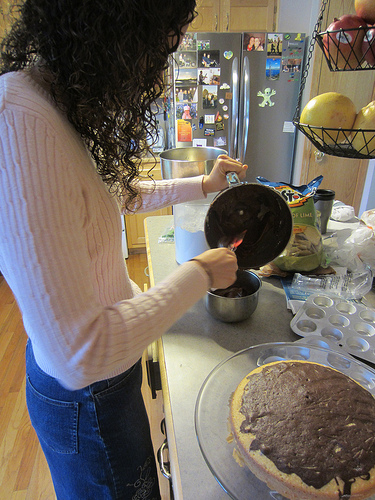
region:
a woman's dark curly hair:
[0, 0, 202, 214]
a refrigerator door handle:
[229, 56, 239, 164]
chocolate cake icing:
[208, 185, 280, 265]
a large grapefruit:
[296, 92, 357, 145]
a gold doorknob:
[313, 147, 323, 161]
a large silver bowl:
[157, 145, 230, 183]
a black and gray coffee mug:
[311, 189, 334, 236]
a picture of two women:
[240, 31, 267, 52]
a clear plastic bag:
[290, 267, 372, 294]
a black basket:
[295, 118, 373, 158]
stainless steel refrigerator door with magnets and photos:
[242, 31, 296, 170]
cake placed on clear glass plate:
[193, 340, 369, 496]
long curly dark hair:
[66, 19, 160, 204]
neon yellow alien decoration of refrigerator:
[254, 81, 278, 111]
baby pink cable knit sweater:
[0, 69, 204, 385]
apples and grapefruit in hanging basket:
[291, 1, 374, 161]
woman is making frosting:
[196, 157, 291, 322]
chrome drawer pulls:
[157, 435, 173, 485]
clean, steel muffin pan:
[290, 288, 374, 360]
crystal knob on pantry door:
[312, 149, 324, 164]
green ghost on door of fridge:
[251, 83, 287, 108]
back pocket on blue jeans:
[13, 382, 86, 448]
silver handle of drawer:
[140, 436, 187, 474]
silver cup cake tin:
[289, 276, 365, 346]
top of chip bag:
[264, 160, 336, 200]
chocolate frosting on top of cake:
[269, 381, 344, 432]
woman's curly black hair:
[60, 26, 154, 109]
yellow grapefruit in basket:
[289, 85, 346, 124]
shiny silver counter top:
[176, 334, 253, 337]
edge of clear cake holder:
[181, 371, 219, 421]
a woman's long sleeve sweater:
[0, 67, 215, 390]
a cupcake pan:
[289, 288, 373, 362]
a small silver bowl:
[200, 271, 263, 324]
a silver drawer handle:
[155, 439, 171, 481]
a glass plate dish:
[193, 340, 374, 499]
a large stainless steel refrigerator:
[166, 27, 307, 194]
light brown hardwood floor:
[0, 272, 54, 498]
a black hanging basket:
[289, 0, 373, 159]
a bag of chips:
[253, 173, 334, 278]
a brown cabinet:
[221, 1, 275, 30]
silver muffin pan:
[290, 288, 374, 361]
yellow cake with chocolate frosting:
[230, 356, 373, 496]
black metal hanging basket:
[292, 0, 373, 160]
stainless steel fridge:
[165, 26, 308, 187]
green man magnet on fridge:
[255, 86, 276, 110]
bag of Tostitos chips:
[255, 173, 331, 275]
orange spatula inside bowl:
[229, 227, 245, 252]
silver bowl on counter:
[204, 267, 260, 324]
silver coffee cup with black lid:
[312, 186, 334, 234]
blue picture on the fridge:
[265, 57, 280, 84]